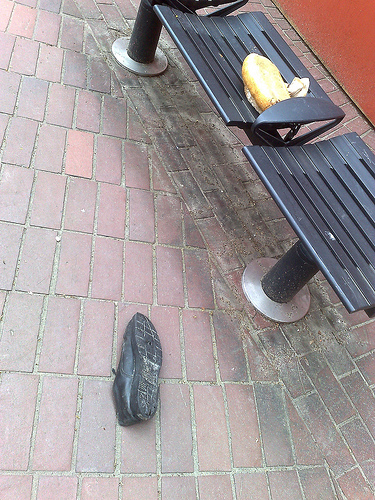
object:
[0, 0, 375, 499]
brick floor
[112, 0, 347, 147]
bench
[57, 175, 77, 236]
lines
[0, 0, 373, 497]
sidewalk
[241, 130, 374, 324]
bench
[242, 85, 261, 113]
foil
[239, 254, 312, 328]
plate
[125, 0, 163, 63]
legs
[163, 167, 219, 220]
bricks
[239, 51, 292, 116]
sandwich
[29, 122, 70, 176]
red brick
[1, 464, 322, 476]
cement grout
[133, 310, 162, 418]
sole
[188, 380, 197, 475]
gray line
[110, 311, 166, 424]
shoe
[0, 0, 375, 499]
ground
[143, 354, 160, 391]
dirt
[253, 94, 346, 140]
arm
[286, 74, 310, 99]
trash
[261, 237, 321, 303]
pole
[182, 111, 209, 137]
dirt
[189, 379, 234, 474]
brick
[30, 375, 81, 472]
brick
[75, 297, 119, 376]
brick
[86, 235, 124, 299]
brick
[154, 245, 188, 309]
brick